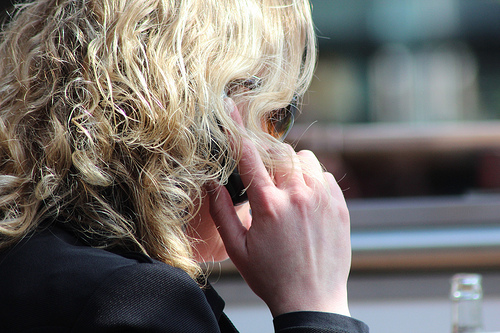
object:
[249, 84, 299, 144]
glasses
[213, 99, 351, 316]
skin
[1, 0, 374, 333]
person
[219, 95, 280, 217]
finger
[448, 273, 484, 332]
bottle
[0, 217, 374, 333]
jacket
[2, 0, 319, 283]
hair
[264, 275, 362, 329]
wrist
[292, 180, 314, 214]
knuckle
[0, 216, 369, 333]
coat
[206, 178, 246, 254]
finger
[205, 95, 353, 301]
hand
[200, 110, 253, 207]
cellphone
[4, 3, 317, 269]
head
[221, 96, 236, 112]
fingernail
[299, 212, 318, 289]
tendon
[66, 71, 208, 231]
curls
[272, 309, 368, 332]
cuff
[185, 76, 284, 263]
face